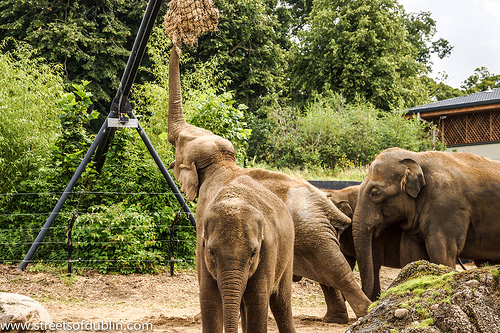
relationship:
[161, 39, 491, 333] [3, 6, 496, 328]
elephants in an enclosure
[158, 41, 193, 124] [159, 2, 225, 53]
trunk reaching for nuts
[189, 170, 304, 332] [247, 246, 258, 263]
elephant has dark eye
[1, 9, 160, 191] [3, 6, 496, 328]
tree next to enclosure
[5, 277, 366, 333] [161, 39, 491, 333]
dirt under elephants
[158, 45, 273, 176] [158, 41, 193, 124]
elephant has trunk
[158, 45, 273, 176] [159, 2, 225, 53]
elephant reaching for food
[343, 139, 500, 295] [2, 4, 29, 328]
elephant facing left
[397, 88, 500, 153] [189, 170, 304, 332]
house for elephant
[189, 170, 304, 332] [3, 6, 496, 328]
elephant in enclosure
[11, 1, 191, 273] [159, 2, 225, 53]
pole with food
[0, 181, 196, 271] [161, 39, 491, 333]
fence to keep elephants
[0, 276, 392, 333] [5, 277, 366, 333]
dirt has dirt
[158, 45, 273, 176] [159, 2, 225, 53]
elephant reaching nuts